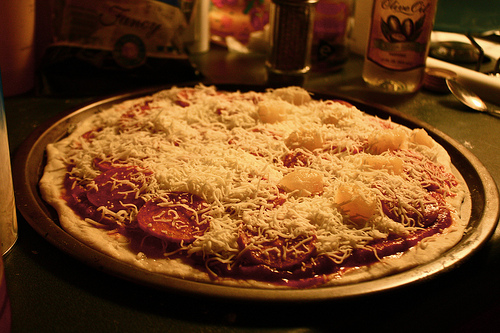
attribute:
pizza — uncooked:
[32, 80, 495, 300]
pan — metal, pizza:
[315, 262, 375, 302]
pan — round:
[24, 77, 498, 302]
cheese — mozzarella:
[161, 112, 278, 192]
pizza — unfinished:
[43, 80, 473, 290]